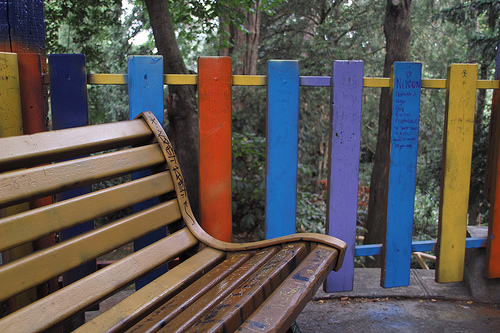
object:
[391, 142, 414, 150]
writing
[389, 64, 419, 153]
graffiti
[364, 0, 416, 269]
trunk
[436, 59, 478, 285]
post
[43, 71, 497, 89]
beam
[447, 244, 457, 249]
nail post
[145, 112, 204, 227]
writing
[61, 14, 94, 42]
leaves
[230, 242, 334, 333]
graffiti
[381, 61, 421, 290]
blue fence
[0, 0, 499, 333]
patio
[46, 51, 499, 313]
fence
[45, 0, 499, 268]
tree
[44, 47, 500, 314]
picket fence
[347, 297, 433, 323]
cement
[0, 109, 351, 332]
bench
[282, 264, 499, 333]
ground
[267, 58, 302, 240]
fence post